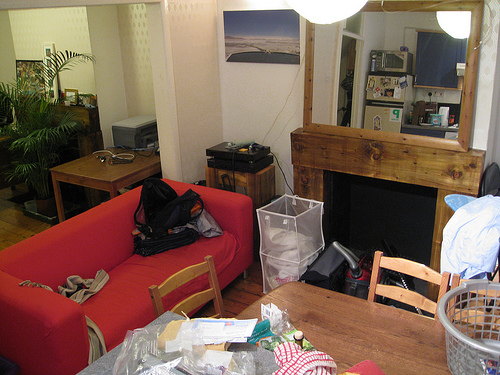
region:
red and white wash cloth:
[283, 333, 330, 373]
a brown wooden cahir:
[101, 245, 233, 350]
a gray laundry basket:
[411, 276, 493, 367]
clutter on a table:
[147, 280, 378, 370]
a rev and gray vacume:
[305, 238, 391, 313]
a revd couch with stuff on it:
[30, 223, 224, 368]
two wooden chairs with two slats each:
[47, 247, 459, 373]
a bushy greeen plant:
[2, 46, 94, 183]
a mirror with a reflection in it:
[244, 27, 480, 180]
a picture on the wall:
[210, 20, 300, 88]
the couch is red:
[110, 128, 242, 318]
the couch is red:
[28, 148, 199, 338]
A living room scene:
[10, 5, 493, 373]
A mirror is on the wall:
[295, 0, 480, 155]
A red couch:
[2, 155, 257, 371]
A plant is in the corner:
[1, 35, 93, 215]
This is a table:
[207, 250, 467, 370]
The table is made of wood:
[292, 280, 352, 331]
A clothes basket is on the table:
[435, 265, 495, 371]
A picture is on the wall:
[215, 5, 305, 65]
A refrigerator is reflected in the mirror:
[357, 70, 412, 130]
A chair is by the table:
[362, 240, 449, 330]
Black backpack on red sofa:
[132, 179, 211, 244]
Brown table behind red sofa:
[40, 142, 164, 226]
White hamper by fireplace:
[249, 182, 337, 297]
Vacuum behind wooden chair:
[325, 235, 382, 297]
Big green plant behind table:
[0, 36, 93, 219]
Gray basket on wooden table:
[435, 277, 499, 374]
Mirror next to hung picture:
[291, 0, 485, 150]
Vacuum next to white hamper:
[330, 237, 383, 301]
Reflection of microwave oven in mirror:
[370, 48, 413, 75]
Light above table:
[277, 0, 369, 27]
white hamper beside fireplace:
[254, 193, 322, 303]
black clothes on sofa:
[103, 174, 223, 262]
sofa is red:
[4, 174, 277, 331]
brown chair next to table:
[152, 242, 252, 342]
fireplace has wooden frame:
[303, 118, 493, 280]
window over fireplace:
[283, 15, 497, 166]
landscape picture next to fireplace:
[183, 2, 337, 83]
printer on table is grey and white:
[98, 108, 181, 157]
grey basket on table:
[398, 264, 495, 348]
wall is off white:
[136, 3, 292, 184]